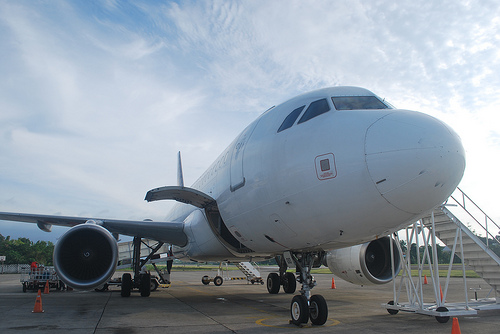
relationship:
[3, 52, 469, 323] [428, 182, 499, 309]
plane has stairs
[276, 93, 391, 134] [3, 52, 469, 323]
cockpit on plane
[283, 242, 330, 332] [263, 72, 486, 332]
landing gear on front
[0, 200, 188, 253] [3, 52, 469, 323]
wing on plane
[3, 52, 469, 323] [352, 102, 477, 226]
plane has nose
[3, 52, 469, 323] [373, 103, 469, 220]
plane has nose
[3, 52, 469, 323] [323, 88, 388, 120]
plane has window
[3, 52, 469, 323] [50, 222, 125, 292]
plane has engine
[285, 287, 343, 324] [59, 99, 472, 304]
wheels under plane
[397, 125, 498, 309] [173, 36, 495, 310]
stairs next plane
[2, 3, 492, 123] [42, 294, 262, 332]
sky above land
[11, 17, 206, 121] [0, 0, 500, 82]
clouds in sky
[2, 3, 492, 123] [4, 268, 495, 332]
sky above land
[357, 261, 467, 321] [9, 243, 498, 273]
trees on distance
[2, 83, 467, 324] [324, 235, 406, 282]
airplane has jet engine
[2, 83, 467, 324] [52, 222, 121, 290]
airplane has engine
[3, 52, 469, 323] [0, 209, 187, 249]
plane has right wing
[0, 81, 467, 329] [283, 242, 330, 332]
jet has landing gear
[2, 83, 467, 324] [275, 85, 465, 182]
airplane has windshield